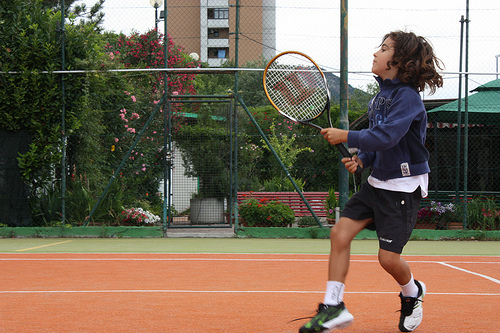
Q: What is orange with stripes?
A: Tennis court.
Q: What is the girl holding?
A: Racket.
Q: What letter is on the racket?
A: W.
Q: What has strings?
A: Racket.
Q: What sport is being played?
A: Tennis.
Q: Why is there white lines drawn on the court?
A: To distinguish boundaries.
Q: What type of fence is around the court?
A: Chain linked.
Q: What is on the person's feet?
A: Tennis shoes.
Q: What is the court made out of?
A: Clay.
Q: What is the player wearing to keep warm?
A: A blue jacket.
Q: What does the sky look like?
A: Overcast.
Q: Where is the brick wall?
A: Behind the chain linked fence.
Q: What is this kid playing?
A: Tennis.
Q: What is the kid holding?
A: Racket.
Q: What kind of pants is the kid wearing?
A: Shorts.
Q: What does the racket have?
A: Strings.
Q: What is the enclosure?
A: Fence.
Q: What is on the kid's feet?
A: Sneakers.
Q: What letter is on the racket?
A: W.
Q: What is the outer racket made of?
A: Metal.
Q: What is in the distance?
A: Building.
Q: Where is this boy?
A: On a tennis court.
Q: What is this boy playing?
A: Tennis.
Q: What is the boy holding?
A: A tennis racket.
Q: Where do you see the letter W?
A: On the tennis racket.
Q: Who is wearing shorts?
A: The boy.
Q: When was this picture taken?
A: Daytime.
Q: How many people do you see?
A: 1.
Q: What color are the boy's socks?
A: White.